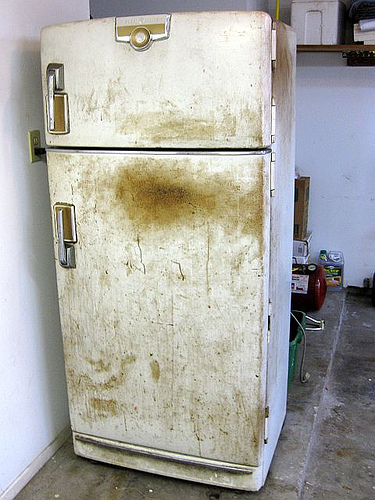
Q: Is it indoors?
A: Yes, it is indoors.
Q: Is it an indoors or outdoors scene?
A: It is indoors.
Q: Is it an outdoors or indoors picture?
A: It is indoors.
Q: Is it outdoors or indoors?
A: It is indoors.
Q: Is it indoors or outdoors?
A: It is indoors.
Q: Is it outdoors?
A: No, it is indoors.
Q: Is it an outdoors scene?
A: No, it is indoors.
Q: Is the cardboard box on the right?
A: Yes, the box is on the right of the image.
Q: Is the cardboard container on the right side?
A: Yes, the box is on the right of the image.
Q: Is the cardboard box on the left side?
A: No, the box is on the right of the image.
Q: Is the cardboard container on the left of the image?
A: No, the box is on the right of the image.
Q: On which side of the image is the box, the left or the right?
A: The box is on the right of the image.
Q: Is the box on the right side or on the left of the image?
A: The box is on the right of the image.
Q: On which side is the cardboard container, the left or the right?
A: The box is on the right of the image.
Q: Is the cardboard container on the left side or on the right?
A: The box is on the right of the image.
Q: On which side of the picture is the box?
A: The box is on the right of the image.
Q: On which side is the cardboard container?
A: The box is on the right of the image.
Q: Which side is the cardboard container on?
A: The box is on the right of the image.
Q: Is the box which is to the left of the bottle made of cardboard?
A: Yes, the box is made of cardboard.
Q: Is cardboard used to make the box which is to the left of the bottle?
A: Yes, the box is made of cardboard.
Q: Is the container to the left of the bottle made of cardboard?
A: Yes, the box is made of cardboard.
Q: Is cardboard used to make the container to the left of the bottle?
A: Yes, the box is made of cardboard.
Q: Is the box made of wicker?
A: No, the box is made of cardboard.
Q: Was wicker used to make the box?
A: No, the box is made of cardboard.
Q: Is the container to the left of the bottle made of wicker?
A: No, the box is made of cardboard.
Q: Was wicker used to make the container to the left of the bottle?
A: No, the box is made of cardboard.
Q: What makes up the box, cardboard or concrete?
A: The box is made of cardboard.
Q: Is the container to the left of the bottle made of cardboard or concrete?
A: The box is made of cardboard.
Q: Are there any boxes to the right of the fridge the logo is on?
A: Yes, there is a box to the right of the freezer.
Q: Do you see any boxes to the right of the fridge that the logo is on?
A: Yes, there is a box to the right of the freezer.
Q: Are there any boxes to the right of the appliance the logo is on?
A: Yes, there is a box to the right of the freezer.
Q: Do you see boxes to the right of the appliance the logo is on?
A: Yes, there is a box to the right of the freezer.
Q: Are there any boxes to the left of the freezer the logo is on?
A: No, the box is to the right of the refrigerator.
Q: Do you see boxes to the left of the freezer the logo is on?
A: No, the box is to the right of the refrigerator.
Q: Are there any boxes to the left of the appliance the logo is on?
A: No, the box is to the right of the refrigerator.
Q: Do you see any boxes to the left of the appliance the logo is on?
A: No, the box is to the right of the refrigerator.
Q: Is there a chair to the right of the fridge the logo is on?
A: No, there is a box to the right of the fridge.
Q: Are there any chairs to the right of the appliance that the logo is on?
A: No, there is a box to the right of the fridge.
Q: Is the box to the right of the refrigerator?
A: Yes, the box is to the right of the refrigerator.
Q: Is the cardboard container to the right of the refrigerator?
A: Yes, the box is to the right of the refrigerator.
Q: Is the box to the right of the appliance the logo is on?
A: Yes, the box is to the right of the refrigerator.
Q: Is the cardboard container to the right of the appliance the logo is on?
A: Yes, the box is to the right of the refrigerator.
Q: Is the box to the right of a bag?
A: No, the box is to the right of the refrigerator.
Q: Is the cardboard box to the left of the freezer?
A: No, the box is to the right of the freezer.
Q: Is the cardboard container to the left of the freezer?
A: No, the box is to the right of the freezer.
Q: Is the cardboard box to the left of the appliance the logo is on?
A: No, the box is to the right of the freezer.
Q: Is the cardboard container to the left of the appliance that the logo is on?
A: No, the box is to the right of the freezer.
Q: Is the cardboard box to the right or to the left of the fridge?
A: The box is to the right of the fridge.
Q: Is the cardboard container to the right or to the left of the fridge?
A: The box is to the right of the fridge.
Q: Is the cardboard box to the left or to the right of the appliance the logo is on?
A: The box is to the right of the fridge.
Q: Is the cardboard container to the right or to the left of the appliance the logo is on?
A: The box is to the right of the fridge.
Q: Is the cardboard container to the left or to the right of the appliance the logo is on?
A: The box is to the right of the fridge.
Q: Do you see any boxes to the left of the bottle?
A: Yes, there is a box to the left of the bottle.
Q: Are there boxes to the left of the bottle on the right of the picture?
A: Yes, there is a box to the left of the bottle.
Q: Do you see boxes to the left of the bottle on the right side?
A: Yes, there is a box to the left of the bottle.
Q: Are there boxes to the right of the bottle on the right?
A: No, the box is to the left of the bottle.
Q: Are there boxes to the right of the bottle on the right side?
A: No, the box is to the left of the bottle.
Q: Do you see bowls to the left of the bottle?
A: No, there is a box to the left of the bottle.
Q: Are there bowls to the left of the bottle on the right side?
A: No, there is a box to the left of the bottle.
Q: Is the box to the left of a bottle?
A: Yes, the box is to the left of a bottle.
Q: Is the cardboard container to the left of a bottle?
A: Yes, the box is to the left of a bottle.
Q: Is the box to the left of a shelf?
A: No, the box is to the left of a bottle.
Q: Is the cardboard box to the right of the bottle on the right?
A: No, the box is to the left of the bottle.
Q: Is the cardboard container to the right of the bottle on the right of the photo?
A: No, the box is to the left of the bottle.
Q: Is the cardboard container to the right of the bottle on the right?
A: No, the box is to the left of the bottle.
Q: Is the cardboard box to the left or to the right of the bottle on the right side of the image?
A: The box is to the left of the bottle.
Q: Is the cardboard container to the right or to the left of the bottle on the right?
A: The box is to the left of the bottle.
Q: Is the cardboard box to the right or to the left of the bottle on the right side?
A: The box is to the left of the bottle.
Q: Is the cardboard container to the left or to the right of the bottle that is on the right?
A: The box is to the left of the bottle.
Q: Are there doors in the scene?
A: Yes, there is a door.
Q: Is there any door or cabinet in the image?
A: Yes, there is a door.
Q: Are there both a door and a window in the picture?
A: No, there is a door but no windows.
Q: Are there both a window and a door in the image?
A: No, there is a door but no windows.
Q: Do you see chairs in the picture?
A: No, there are no chairs.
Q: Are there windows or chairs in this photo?
A: No, there are no chairs or windows.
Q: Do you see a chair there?
A: No, there are no chairs.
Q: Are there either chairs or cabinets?
A: No, there are no chairs or cabinets.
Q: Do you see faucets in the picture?
A: No, there are no faucets.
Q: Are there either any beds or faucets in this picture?
A: No, there are no faucets or beds.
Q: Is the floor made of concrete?
A: Yes, the floor is made of concrete.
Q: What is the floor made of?
A: The floor is made of concrete.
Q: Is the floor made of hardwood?
A: No, the floor is made of concrete.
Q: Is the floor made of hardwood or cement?
A: The floor is made of cement.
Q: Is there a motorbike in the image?
A: No, there are no motorcycles.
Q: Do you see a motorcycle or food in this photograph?
A: No, there are no motorcycles or food.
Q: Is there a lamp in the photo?
A: No, there are no lamps.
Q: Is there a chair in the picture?
A: No, there are no chairs.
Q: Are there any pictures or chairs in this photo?
A: No, there are no chairs or pictures.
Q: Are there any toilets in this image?
A: No, there are no toilets.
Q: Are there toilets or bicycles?
A: No, there are no toilets or bicycles.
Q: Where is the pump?
A: The pump is on the floor.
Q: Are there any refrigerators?
A: Yes, there is a refrigerator.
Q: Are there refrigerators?
A: Yes, there is a refrigerator.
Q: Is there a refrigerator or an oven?
A: Yes, there is a refrigerator.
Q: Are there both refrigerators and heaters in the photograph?
A: No, there is a refrigerator but no heaters.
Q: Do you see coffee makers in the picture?
A: No, there are no coffee makers.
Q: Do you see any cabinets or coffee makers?
A: No, there are no coffee makers or cabinets.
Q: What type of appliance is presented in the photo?
A: The appliance is a refrigerator.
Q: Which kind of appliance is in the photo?
A: The appliance is a refrigerator.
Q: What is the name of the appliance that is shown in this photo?
A: The appliance is a refrigerator.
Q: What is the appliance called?
A: The appliance is a refrigerator.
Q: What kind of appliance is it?
A: The appliance is a refrigerator.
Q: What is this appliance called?
A: This is a refrigerator.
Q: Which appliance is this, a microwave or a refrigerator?
A: This is a refrigerator.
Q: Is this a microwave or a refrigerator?
A: This is a refrigerator.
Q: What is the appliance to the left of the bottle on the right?
A: The appliance is a refrigerator.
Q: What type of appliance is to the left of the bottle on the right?
A: The appliance is a refrigerator.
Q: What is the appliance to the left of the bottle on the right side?
A: The appliance is a refrigerator.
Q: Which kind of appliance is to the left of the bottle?
A: The appliance is a refrigerator.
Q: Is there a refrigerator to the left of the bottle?
A: Yes, there is a refrigerator to the left of the bottle.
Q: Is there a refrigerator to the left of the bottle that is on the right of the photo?
A: Yes, there is a refrigerator to the left of the bottle.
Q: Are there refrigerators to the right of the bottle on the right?
A: No, the refrigerator is to the left of the bottle.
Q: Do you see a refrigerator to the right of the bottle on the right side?
A: No, the refrigerator is to the left of the bottle.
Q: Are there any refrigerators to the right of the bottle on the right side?
A: No, the refrigerator is to the left of the bottle.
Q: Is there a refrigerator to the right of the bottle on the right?
A: No, the refrigerator is to the left of the bottle.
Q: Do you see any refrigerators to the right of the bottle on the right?
A: No, the refrigerator is to the left of the bottle.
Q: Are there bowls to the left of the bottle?
A: No, there is a refrigerator to the left of the bottle.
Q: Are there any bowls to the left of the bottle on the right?
A: No, there is a refrigerator to the left of the bottle.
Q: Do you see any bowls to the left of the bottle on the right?
A: No, there is a refrigerator to the left of the bottle.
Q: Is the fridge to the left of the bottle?
A: Yes, the fridge is to the left of the bottle.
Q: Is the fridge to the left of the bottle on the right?
A: Yes, the fridge is to the left of the bottle.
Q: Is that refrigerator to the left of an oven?
A: No, the refrigerator is to the left of the bottle.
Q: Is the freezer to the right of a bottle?
A: No, the freezer is to the left of a bottle.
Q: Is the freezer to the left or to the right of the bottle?
A: The freezer is to the left of the bottle.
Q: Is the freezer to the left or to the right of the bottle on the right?
A: The freezer is to the left of the bottle.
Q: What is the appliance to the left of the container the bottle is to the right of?
A: The appliance is a refrigerator.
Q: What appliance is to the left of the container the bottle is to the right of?
A: The appliance is a refrigerator.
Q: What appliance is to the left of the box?
A: The appliance is a refrigerator.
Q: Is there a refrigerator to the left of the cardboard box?
A: Yes, there is a refrigerator to the left of the box.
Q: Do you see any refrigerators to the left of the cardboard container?
A: Yes, there is a refrigerator to the left of the box.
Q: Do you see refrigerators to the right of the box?
A: No, the refrigerator is to the left of the box.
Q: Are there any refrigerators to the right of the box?
A: No, the refrigerator is to the left of the box.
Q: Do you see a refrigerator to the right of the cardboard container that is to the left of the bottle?
A: No, the refrigerator is to the left of the box.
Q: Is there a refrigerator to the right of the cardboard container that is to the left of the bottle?
A: No, the refrigerator is to the left of the box.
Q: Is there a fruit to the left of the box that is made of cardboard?
A: No, there is a refrigerator to the left of the box.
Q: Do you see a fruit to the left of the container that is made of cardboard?
A: No, there is a refrigerator to the left of the box.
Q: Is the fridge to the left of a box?
A: Yes, the fridge is to the left of a box.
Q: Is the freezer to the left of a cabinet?
A: No, the freezer is to the left of a box.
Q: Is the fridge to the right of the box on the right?
A: No, the fridge is to the left of the box.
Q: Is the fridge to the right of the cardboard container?
A: No, the fridge is to the left of the box.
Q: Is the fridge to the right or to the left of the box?
A: The fridge is to the left of the box.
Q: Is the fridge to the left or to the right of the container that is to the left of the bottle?
A: The fridge is to the left of the box.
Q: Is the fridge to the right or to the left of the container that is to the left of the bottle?
A: The fridge is to the left of the box.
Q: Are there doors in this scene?
A: Yes, there is a door.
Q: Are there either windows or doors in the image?
A: Yes, there is a door.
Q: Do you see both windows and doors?
A: No, there is a door but no windows.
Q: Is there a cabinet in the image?
A: No, there are no cabinets.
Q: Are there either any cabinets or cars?
A: No, there are no cabinets or cars.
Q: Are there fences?
A: No, there are no fences.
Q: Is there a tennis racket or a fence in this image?
A: No, there are no fences or rackets.